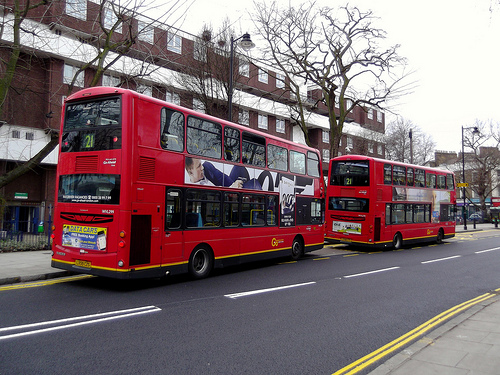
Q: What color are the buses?
A: Red.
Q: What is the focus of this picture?
A: Buses.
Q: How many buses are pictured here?
A: Two.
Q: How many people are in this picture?
A: Zero.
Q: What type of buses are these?
A: Double Decker.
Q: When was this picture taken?
A: Daytime.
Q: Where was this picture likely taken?
A: London.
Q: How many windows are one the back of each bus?
A: Two.